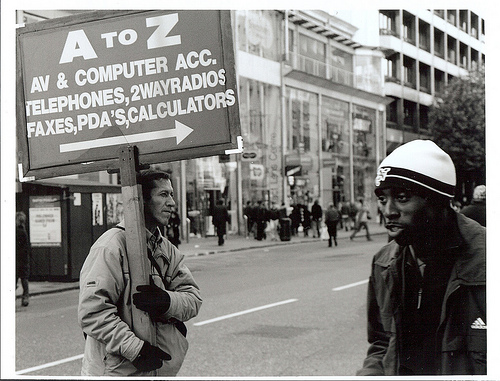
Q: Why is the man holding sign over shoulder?
A: Advertisement.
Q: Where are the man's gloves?
A: On hands.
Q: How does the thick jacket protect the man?
A: Weather.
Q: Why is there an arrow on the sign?
A: Points direction store.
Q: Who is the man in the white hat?
A: Pedestrian walking.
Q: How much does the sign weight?
A: Thirty pounds.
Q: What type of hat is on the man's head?
A: White knit.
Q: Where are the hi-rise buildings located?
A: City street.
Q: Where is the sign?
A: In the man's hands.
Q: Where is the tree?
A: By the building.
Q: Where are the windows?
A: On the building.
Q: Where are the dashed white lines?
A: On the road.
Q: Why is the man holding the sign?
A: Advertising.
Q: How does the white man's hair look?
A: Short.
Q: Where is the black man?
A: By the man with the sign.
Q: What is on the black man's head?
A: White hat.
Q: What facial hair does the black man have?
A: Mustache.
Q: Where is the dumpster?
A: On the sidewalk.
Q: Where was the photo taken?
A: On a street.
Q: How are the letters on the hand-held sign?
A: Spilling over the right frame.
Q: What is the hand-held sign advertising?
A: Audiovisual and computer accessories.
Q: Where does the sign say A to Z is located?
A: To the right.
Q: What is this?
A: A city street and protestor.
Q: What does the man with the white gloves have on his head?
A: Hair.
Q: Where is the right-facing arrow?
A: On the sign held by the man in black gloves.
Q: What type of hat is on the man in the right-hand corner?
A: A knit hat.